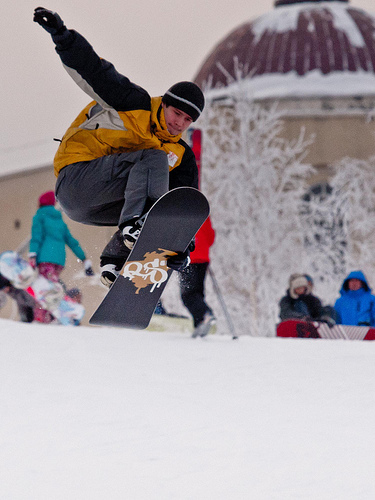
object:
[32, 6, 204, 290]
man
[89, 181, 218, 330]
snowboard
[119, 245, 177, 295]
logo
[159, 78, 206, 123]
cap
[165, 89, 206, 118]
stripe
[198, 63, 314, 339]
trees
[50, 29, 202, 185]
jacket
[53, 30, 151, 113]
arm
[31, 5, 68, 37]
glove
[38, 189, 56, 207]
cap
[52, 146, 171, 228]
pants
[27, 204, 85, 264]
jacket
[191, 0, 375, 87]
roof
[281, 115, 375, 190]
wall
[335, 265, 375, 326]
jacket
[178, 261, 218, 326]
pants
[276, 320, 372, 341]
board